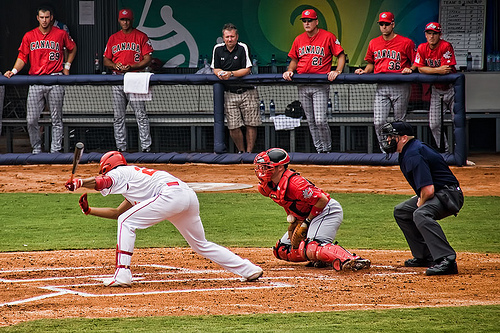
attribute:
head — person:
[243, 145, 299, 197]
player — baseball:
[66, 150, 260, 286]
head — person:
[98, 150, 127, 176]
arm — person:
[65, 176, 112, 192]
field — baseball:
[8, 183, 497, 260]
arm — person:
[290, 183, 331, 240]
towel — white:
[118, 66, 159, 109]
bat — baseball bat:
[66, 144, 88, 175]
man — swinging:
[49, 142, 276, 310]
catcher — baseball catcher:
[253, 146, 372, 272]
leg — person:
[103, 192, 187, 286]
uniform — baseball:
[285, 28, 345, 152]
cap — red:
[296, 5, 321, 23]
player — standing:
[20, 5, 73, 127]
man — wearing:
[282, 8, 345, 153]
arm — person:
[80, 187, 127, 227]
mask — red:
[250, 142, 295, 188]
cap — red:
[114, 7, 136, 28]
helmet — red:
[83, 147, 125, 167]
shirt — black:
[396, 143, 435, 191]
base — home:
[60, 257, 210, 296]